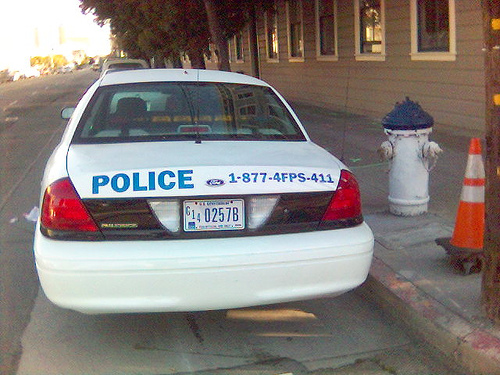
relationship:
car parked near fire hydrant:
[31, 67, 375, 318] [376, 95, 446, 215]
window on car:
[75, 79, 303, 142] [28, 59, 386, 324]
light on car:
[39, 173, 106, 242] [28, 59, 386, 324]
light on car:
[316, 170, 364, 232] [28, 59, 386, 324]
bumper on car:
[35, 215, 377, 316] [28, 59, 386, 324]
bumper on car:
[27, 223, 377, 317] [28, 59, 386, 324]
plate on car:
[182, 198, 245, 231] [28, 59, 386, 324]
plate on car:
[176, 191, 246, 237] [28, 59, 386, 324]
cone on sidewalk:
[445, 133, 491, 250] [227, 88, 497, 368]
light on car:
[324, 167, 366, 231] [28, 59, 386, 324]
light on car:
[31, 172, 100, 242] [28, 59, 386, 324]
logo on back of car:
[201, 179, 226, 188] [32, 148, 378, 313]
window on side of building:
[350, 10, 392, 61] [160, 0, 493, 148]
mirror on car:
[58, 104, 74, 121] [28, 59, 386, 324]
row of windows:
[190, 10, 458, 58] [198, 7, 463, 63]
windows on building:
[198, 7, 463, 63] [173, 12, 478, 122]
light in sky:
[14, 13, 88, 68] [12, 11, 103, 71]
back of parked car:
[30, 73, 373, 313] [28, 59, 386, 324]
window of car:
[74, 79, 304, 139] [28, 59, 386, 324]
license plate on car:
[175, 195, 252, 240] [31, 67, 375, 318]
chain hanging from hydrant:
[422, 159, 440, 175] [376, 90, 442, 211]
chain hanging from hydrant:
[382, 160, 391, 173] [376, 90, 442, 211]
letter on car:
[90, 168, 110, 197] [28, 59, 386, 324]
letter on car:
[108, 173, 130, 193] [28, 59, 386, 324]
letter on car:
[147, 171, 156, 190] [28, 59, 386, 324]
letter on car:
[156, 169, 175, 190] [28, 59, 386, 324]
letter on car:
[175, 168, 193, 189] [28, 59, 386, 324]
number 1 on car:
[229, 169, 239, 182] [28, 59, 386, 324]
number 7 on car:
[250, 168, 257, 186] [28, 59, 386, 324]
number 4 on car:
[273, 169, 281, 184] [21, 71, 375, 332]